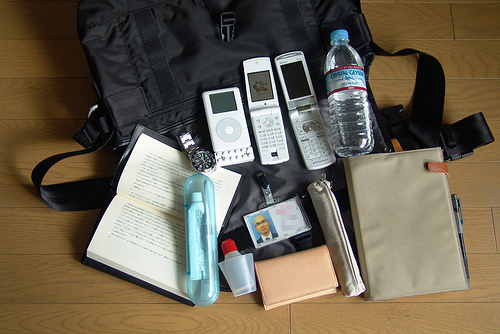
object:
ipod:
[198, 85, 257, 166]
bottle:
[324, 26, 379, 157]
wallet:
[252, 243, 342, 311]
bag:
[30, 2, 493, 210]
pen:
[446, 193, 472, 287]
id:
[241, 195, 314, 250]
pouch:
[307, 179, 366, 296]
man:
[244, 210, 280, 245]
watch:
[171, 134, 218, 176]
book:
[86, 133, 242, 301]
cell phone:
[275, 50, 334, 169]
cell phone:
[242, 55, 289, 165]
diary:
[348, 145, 469, 306]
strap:
[175, 132, 198, 151]